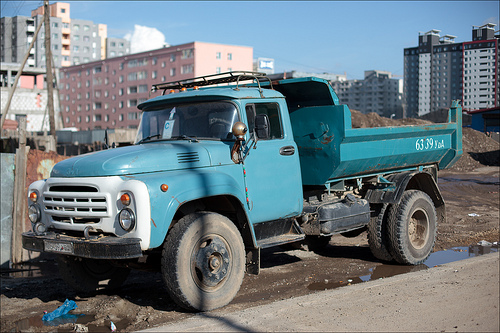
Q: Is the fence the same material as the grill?
A: No, the fence is made of wood and the grill is made of metal.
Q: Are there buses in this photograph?
A: No, there are no buses.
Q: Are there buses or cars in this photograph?
A: No, there are no buses or cars.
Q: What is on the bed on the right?
A: The number is on the bed.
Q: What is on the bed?
A: The number is on the bed.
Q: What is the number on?
A: The number is on the bed.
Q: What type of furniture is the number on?
A: The number is on the bed.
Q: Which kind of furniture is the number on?
A: The number is on the bed.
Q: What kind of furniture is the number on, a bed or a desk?
A: The number is on a bed.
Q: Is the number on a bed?
A: Yes, the number is on a bed.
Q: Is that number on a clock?
A: No, the number is on a bed.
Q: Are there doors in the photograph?
A: Yes, there is a door.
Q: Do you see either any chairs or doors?
A: Yes, there is a door.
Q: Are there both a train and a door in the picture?
A: No, there is a door but no trains.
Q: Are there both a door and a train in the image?
A: No, there is a door but no trains.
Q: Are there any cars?
A: No, there are no cars.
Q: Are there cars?
A: No, there are no cars.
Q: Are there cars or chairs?
A: No, there are no cars or chairs.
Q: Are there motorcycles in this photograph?
A: No, there are no motorcycles.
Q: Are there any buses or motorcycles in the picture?
A: No, there are no motorcycles or buses.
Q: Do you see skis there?
A: No, there are no skis.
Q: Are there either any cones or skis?
A: No, there are no skis or cones.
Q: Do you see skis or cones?
A: No, there are no skis or cones.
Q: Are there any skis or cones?
A: No, there are no skis or cones.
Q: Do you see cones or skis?
A: No, there are no skis or cones.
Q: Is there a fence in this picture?
A: Yes, there is a fence.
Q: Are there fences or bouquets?
A: Yes, there is a fence.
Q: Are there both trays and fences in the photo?
A: No, there is a fence but no trays.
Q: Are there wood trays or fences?
A: Yes, there is a wood fence.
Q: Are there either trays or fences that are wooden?
A: Yes, the fence is wooden.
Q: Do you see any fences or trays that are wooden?
A: Yes, the fence is wooden.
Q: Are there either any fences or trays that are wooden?
A: Yes, the fence is wooden.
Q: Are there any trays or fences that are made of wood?
A: Yes, the fence is made of wood.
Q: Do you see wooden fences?
A: Yes, there is a wood fence.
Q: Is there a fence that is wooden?
A: Yes, there is a fence that is wooden.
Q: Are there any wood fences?
A: Yes, there is a fence that is made of wood.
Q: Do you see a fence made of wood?
A: Yes, there is a fence that is made of wood.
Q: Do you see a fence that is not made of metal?
A: Yes, there is a fence that is made of wood.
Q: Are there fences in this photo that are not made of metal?
A: Yes, there is a fence that is made of wood.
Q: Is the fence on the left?
A: Yes, the fence is on the left of the image.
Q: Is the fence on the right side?
A: No, the fence is on the left of the image.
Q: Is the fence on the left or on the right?
A: The fence is on the left of the image.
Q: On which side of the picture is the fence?
A: The fence is on the left of the image.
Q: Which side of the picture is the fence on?
A: The fence is on the left of the image.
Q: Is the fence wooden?
A: Yes, the fence is wooden.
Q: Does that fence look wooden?
A: Yes, the fence is wooden.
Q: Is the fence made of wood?
A: Yes, the fence is made of wood.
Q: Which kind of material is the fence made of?
A: The fence is made of wood.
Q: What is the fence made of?
A: The fence is made of wood.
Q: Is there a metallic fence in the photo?
A: No, there is a fence but it is wooden.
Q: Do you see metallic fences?
A: No, there is a fence but it is wooden.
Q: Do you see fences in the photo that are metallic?
A: No, there is a fence but it is wooden.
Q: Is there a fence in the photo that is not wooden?
A: No, there is a fence but it is wooden.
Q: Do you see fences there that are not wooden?
A: No, there is a fence but it is wooden.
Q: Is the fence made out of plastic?
A: No, the fence is made of wood.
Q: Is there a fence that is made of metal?
A: No, there is a fence but it is made of wood.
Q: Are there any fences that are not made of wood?
A: No, there is a fence but it is made of wood.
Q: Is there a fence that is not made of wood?
A: No, there is a fence but it is made of wood.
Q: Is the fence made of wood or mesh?
A: The fence is made of wood.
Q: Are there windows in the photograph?
A: Yes, there are windows.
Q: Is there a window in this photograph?
A: Yes, there are windows.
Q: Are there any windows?
A: Yes, there are windows.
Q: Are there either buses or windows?
A: Yes, there are windows.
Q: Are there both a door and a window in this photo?
A: Yes, there are both a window and a door.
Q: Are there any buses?
A: No, there are no buses.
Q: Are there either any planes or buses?
A: No, there are no buses or planes.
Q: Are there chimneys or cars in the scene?
A: No, there are no cars or chimneys.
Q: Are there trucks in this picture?
A: Yes, there is a truck.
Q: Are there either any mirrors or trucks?
A: Yes, there is a truck.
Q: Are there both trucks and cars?
A: No, there is a truck but no cars.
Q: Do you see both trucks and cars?
A: No, there is a truck but no cars.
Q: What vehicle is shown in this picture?
A: The vehicle is a truck.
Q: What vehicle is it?
A: The vehicle is a truck.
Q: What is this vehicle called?
A: This is a truck.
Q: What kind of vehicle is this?
A: This is a truck.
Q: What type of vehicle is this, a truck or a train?
A: This is a truck.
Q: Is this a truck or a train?
A: This is a truck.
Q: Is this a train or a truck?
A: This is a truck.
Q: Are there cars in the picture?
A: No, there are no cars.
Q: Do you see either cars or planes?
A: No, there are no cars or planes.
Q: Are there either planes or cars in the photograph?
A: No, there are no cars or planes.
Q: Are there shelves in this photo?
A: No, there are no shelves.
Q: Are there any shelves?
A: No, there are no shelves.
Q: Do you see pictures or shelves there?
A: No, there are no shelves or pictures.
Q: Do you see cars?
A: No, there are no cars.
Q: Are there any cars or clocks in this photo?
A: No, there are no cars or clocks.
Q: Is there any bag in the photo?
A: Yes, there is a bag.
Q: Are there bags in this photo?
A: Yes, there is a bag.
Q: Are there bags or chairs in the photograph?
A: Yes, there is a bag.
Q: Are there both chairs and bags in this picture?
A: No, there is a bag but no chairs.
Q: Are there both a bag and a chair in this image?
A: No, there is a bag but no chairs.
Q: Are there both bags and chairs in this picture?
A: No, there is a bag but no chairs.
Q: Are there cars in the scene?
A: No, there are no cars.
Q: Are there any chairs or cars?
A: No, there are no cars or chairs.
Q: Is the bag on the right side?
A: No, the bag is on the left of the image.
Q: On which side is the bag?
A: The bag is on the left of the image.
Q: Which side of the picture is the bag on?
A: The bag is on the left of the image.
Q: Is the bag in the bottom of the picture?
A: Yes, the bag is in the bottom of the image.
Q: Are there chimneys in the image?
A: No, there are no chimneys.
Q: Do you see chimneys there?
A: No, there are no chimneys.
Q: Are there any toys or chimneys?
A: No, there are no chimneys or toys.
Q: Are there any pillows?
A: No, there are no pillows.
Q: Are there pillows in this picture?
A: No, there are no pillows.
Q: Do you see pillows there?
A: No, there are no pillows.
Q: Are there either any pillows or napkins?
A: No, there are no pillows or napkins.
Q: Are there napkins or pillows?
A: No, there are no pillows or napkins.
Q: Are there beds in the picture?
A: Yes, there is a bed.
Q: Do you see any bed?
A: Yes, there is a bed.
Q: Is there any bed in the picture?
A: Yes, there is a bed.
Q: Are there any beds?
A: Yes, there is a bed.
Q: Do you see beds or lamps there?
A: Yes, there is a bed.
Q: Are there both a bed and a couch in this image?
A: No, there is a bed but no couches.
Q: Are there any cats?
A: No, there are no cats.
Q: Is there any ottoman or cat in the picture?
A: No, there are no cats or ottomen.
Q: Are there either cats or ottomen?
A: No, there are no cats or ottomen.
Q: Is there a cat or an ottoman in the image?
A: No, there are no cats or ottomen.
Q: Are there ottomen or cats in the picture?
A: No, there are no cats or ottomen.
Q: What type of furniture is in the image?
A: The furniture is a bed.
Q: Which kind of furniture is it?
A: The piece of furniture is a bed.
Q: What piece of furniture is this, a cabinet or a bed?
A: That is a bed.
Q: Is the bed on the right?
A: Yes, the bed is on the right of the image.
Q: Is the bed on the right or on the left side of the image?
A: The bed is on the right of the image.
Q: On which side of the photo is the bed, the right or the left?
A: The bed is on the right of the image.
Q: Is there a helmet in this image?
A: No, there are no helmets.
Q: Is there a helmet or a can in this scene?
A: No, there are no helmets or cans.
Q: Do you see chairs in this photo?
A: No, there are no chairs.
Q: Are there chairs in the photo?
A: No, there are no chairs.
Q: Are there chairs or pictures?
A: No, there are no chairs or pictures.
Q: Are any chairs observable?
A: No, there are no chairs.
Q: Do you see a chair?
A: No, there are no chairs.